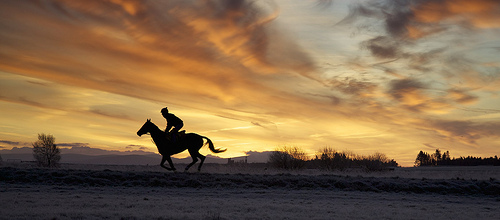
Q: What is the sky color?
A: Orange.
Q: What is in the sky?
A: Clouds.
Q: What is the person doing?
A: Riding a horse.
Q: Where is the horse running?
A: On ground.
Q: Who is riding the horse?
A: A person.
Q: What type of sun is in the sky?
A: Sunset.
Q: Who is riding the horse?
A: A man.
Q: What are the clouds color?
A: Orange and white.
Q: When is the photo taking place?
A: During a sunset.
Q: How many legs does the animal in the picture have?
A: Four.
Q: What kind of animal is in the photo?
A: Horse.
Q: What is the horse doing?
A: Running.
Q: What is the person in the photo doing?
A: Riding a horse.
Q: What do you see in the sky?
A: Clouds.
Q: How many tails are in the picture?
A: One.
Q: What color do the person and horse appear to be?
A: Black.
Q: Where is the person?
A: On top of the horse.